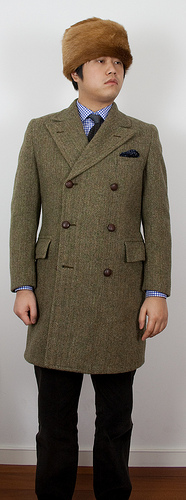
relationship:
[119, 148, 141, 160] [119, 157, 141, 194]
hankie hanging out of pocket square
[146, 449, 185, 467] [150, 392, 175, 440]
baseboard against wall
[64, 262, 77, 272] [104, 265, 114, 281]
hole with no button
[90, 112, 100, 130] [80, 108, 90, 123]
tie against shirt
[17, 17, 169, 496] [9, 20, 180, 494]
man modeling outfit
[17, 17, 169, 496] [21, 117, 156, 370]
man dressed for cold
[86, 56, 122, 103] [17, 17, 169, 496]
face of a man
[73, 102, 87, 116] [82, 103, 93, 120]
collar of a shirt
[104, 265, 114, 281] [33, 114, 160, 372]
button on jacket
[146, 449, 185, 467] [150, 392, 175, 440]
baseboard of wall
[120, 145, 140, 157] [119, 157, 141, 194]
handkerchief in pocket square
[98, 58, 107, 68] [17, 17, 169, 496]
eye of man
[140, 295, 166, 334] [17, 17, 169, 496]
hand of man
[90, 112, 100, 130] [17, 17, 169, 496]
tie of man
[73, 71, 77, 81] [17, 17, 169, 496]
ear of man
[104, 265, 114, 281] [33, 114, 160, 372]
button on a jacket